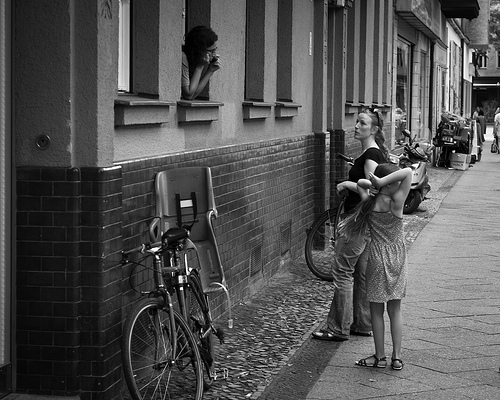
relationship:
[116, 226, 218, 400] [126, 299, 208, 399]
bicycle has wheel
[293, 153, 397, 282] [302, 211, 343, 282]
bicycle has tire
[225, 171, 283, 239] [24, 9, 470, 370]
wall of building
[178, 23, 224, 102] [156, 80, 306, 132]
lady hanging on ledge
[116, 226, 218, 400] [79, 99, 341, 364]
bicycle against wall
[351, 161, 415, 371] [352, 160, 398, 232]
girl holding hair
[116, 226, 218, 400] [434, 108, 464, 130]
bicycle with luggage luggage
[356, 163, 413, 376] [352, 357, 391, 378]
girl has sandal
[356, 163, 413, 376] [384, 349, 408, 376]
girl has sandal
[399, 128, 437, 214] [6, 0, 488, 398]
scooter next to building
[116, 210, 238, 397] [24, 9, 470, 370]
bicycle up against building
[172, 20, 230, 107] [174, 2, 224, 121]
lady in window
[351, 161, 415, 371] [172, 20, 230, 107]
girl speaking to lady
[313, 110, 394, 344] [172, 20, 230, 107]
lady speaking to lady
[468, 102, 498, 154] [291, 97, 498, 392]
people further sidewalk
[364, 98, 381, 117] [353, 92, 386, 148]
sunglasses on head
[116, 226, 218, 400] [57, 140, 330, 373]
bicycle leaning against wall.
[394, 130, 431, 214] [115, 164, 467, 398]
scooter parked on walk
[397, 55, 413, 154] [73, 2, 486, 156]
door in building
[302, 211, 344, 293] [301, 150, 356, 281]
tire mounted on bicycle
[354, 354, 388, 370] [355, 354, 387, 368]
sandal worn on foot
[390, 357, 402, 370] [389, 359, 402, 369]
sandal worn on foot